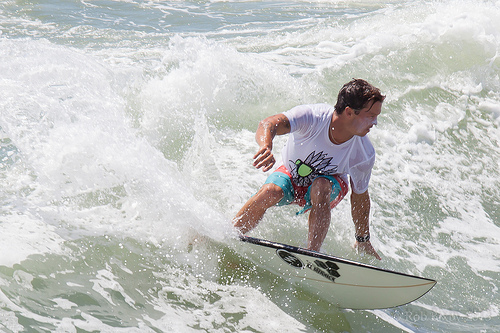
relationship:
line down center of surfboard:
[182, 197, 377, 296] [203, 208, 493, 322]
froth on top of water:
[30, 48, 245, 228] [35, 43, 496, 323]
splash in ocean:
[33, 82, 199, 236] [2, 1, 498, 331]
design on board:
[275, 247, 340, 284] [233, 232, 438, 314]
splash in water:
[33, 82, 199, 236] [2, 3, 497, 331]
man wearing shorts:
[231, 72, 389, 256] [234, 234, 440, 318]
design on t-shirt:
[287, 150, 338, 187] [281, 103, 376, 194]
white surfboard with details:
[232, 238, 437, 310] [238, 234, 432, 283]